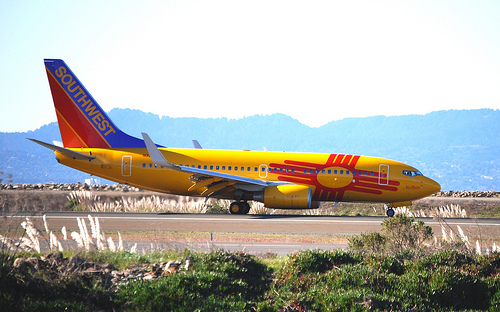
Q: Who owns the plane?
A: Southwest.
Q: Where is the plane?
A: On runway.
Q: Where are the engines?
A: On wings.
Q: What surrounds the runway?
A: Plants.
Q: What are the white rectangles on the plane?
A: Doors.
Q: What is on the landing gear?
A: Tires.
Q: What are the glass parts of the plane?
A: Windows.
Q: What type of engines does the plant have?
A: Jet.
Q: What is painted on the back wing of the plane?
A: The word Southwest.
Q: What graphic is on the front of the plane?
A: The New Mexico state flag logo.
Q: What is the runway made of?
A: Concrete.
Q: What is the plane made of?
A: Metal.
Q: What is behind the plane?
A: Mountains.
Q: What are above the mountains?
A: Sky.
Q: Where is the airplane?
A: On the ground.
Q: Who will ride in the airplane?
A: Passengers.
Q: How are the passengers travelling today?
A: Plane.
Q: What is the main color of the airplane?
A: Yellow.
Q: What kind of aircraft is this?
A: An airplane.